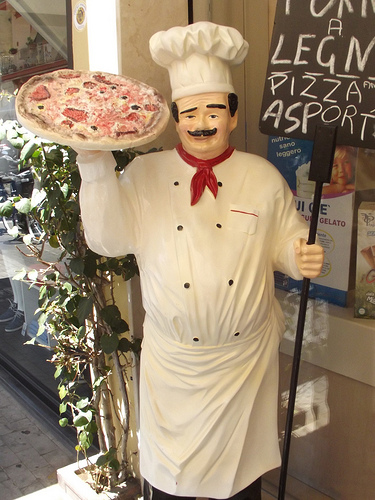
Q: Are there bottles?
A: No, there are no bottles.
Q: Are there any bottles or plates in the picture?
A: No, there are no bottles or plates.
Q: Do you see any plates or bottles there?
A: No, there are no bottles or plates.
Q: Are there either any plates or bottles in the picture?
A: No, there are no bottles or plates.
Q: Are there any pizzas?
A: Yes, there is a pizza.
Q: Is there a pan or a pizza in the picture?
A: Yes, there is a pizza.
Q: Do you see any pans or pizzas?
A: Yes, there is a pizza.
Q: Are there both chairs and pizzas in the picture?
A: No, there is a pizza but no chairs.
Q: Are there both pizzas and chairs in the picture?
A: No, there is a pizza but no chairs.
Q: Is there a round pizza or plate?
A: Yes, there is a round pizza.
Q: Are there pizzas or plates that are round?
A: Yes, the pizza is round.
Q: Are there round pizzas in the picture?
A: Yes, there is a round pizza.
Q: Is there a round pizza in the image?
A: Yes, there is a round pizza.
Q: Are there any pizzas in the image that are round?
A: Yes, there is a pizza that is round.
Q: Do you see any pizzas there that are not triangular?
A: Yes, there is a round pizza.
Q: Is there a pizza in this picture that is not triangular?
A: Yes, there is a round pizza.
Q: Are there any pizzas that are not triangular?
A: Yes, there is a round pizza.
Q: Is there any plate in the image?
A: No, there are no plates.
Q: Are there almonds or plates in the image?
A: No, there are no plates or almonds.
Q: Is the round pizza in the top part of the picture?
A: Yes, the pizza is in the top of the image.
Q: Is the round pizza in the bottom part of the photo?
A: No, the pizza is in the top of the image.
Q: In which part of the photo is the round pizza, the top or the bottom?
A: The pizza is in the top of the image.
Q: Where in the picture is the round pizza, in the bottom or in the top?
A: The pizza is in the top of the image.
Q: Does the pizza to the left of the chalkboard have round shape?
A: Yes, the pizza is round.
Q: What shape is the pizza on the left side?
A: The pizza is round.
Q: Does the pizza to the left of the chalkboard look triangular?
A: No, the pizza is round.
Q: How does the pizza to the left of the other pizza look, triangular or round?
A: The pizza is round.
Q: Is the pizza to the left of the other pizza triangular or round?
A: The pizza is round.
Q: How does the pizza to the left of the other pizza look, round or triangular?
A: The pizza is round.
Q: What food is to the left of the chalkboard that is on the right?
A: The food is a pizza.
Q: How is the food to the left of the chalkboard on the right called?
A: The food is a pizza.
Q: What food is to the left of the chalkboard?
A: The food is a pizza.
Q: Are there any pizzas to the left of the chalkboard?
A: Yes, there is a pizza to the left of the chalkboard.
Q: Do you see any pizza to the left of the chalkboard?
A: Yes, there is a pizza to the left of the chalkboard.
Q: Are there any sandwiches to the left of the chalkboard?
A: No, there is a pizza to the left of the chalkboard.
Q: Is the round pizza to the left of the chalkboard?
A: Yes, the pizza is to the left of the chalkboard.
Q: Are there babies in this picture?
A: Yes, there is a baby.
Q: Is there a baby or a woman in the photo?
A: Yes, there is a baby.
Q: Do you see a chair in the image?
A: No, there are no chairs.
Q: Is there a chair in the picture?
A: No, there are no chairs.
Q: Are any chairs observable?
A: No, there are no chairs.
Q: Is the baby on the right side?
A: Yes, the baby is on the right of the image.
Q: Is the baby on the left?
A: No, the baby is on the right of the image.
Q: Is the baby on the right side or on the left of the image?
A: The baby is on the right of the image.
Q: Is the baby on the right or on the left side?
A: The baby is on the right of the image.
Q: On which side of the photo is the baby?
A: The baby is on the right of the image.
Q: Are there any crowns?
A: No, there are no crowns.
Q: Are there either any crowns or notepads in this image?
A: No, there are no crowns or notepads.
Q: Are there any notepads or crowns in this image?
A: No, there are no crowns or notepads.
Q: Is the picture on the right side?
A: Yes, the picture is on the right of the image.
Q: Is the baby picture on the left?
A: No, the picture is on the right of the image.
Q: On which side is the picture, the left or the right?
A: The picture is on the right of the image.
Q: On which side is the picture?
A: The picture is on the right of the image.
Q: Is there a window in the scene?
A: Yes, there is a window.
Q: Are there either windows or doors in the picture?
A: Yes, there is a window.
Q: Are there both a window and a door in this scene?
A: No, there is a window but no doors.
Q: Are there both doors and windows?
A: No, there is a window but no doors.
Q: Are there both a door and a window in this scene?
A: No, there is a window but no doors.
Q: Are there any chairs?
A: No, there are no chairs.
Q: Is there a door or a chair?
A: No, there are no chairs or doors.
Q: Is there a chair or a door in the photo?
A: No, there are no chairs or doors.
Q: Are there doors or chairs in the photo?
A: No, there are no chairs or doors.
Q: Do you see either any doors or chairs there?
A: No, there are no chairs or doors.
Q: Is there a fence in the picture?
A: No, there are no fences.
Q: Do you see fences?
A: No, there are no fences.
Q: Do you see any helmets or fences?
A: No, there are no fences or helmets.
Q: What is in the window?
A: The shoes are in the window.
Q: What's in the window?
A: The shoes are in the window.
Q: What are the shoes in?
A: The shoes are in the window.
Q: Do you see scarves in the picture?
A: Yes, there is a scarf.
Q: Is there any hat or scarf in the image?
A: Yes, there is a scarf.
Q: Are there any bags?
A: No, there are no bags.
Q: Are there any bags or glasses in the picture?
A: No, there are no bags or glasses.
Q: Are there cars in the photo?
A: No, there are no cars.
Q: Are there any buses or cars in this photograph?
A: No, there are no cars or buses.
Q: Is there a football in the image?
A: No, there are no footballs.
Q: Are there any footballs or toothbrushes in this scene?
A: No, there are no footballs or toothbrushes.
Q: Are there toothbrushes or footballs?
A: No, there are no footballs or toothbrushes.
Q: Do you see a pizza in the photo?
A: Yes, there is a pizza.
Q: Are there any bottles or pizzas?
A: Yes, there is a pizza.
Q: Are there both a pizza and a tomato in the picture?
A: No, there is a pizza but no tomatoes.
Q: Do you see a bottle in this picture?
A: No, there are no bottles.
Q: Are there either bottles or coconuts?
A: No, there are no bottles or coconuts.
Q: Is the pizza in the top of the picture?
A: Yes, the pizza is in the top of the image.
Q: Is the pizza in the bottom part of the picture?
A: No, the pizza is in the top of the image.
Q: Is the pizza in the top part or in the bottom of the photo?
A: The pizza is in the top of the image.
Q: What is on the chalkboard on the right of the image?
A: The pizza is on the chalkboard.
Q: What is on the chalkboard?
A: The pizza is on the chalkboard.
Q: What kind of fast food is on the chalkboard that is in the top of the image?
A: The food is a pizza.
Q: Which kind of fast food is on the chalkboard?
A: The food is a pizza.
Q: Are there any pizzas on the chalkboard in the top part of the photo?
A: Yes, there is a pizza on the chalkboard.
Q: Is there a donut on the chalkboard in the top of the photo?
A: No, there is a pizza on the chalkboard.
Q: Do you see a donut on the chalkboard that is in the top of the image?
A: No, there is a pizza on the chalkboard.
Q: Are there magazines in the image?
A: No, there are no magazines.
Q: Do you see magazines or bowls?
A: No, there are no magazines or bowls.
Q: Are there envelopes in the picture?
A: No, there are no envelopes.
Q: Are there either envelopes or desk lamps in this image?
A: No, there are no envelopes or desk lamps.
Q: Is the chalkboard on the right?
A: Yes, the chalkboard is on the right of the image.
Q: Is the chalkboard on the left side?
A: No, the chalkboard is on the right of the image.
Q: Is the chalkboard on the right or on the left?
A: The chalkboard is on the right of the image.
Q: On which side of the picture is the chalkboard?
A: The chalkboard is on the right of the image.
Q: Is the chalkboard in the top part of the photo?
A: Yes, the chalkboard is in the top of the image.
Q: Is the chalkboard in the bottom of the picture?
A: No, the chalkboard is in the top of the image.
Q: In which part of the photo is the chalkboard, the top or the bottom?
A: The chalkboard is in the top of the image.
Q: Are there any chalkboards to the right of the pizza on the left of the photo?
A: Yes, there is a chalkboard to the right of the pizza.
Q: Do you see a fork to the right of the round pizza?
A: No, there is a chalkboard to the right of the pizza.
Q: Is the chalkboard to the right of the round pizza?
A: Yes, the chalkboard is to the right of the pizza.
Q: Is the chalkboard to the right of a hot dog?
A: No, the chalkboard is to the right of the pizza.